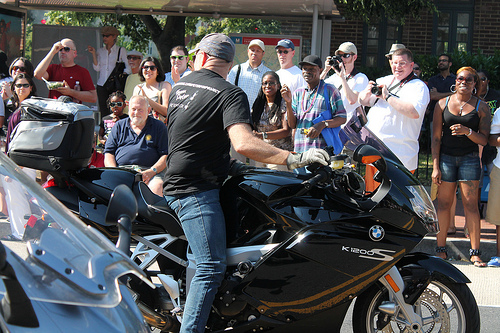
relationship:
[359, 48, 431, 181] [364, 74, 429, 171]
man wearing white shirt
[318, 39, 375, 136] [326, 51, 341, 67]
man holding camera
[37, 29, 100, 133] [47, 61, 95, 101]
man wearing shirt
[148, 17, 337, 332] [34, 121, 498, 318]
man on motorcycle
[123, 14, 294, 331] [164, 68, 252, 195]
man wearing shirt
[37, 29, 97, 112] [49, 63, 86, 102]
man wearing shirt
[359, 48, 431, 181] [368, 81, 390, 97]
man holding camera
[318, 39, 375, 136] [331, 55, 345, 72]
man holding camera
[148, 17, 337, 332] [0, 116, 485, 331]
man on motorcycle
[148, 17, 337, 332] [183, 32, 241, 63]
man wearing hat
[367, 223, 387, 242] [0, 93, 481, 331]
bmw symbol on motorcycle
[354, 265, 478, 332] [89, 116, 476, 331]
wheel on bike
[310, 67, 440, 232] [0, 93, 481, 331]
windshield on motorcycle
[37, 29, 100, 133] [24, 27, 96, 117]
man wearing shirt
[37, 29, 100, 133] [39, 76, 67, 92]
man holding salad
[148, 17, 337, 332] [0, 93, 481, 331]
man on motorcycle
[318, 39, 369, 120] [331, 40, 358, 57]
man wearing hat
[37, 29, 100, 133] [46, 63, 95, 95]
man wearing shirt